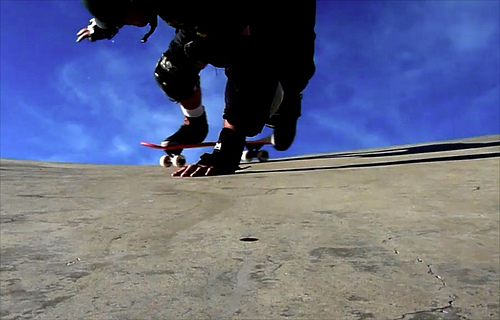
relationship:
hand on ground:
[173, 157, 239, 185] [0, 160, 499, 318]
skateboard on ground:
[140, 138, 271, 165] [0, 160, 499, 318]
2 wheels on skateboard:
[159, 155, 188, 166] [140, 138, 271, 165]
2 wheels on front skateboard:
[159, 155, 188, 166] [140, 138, 271, 165]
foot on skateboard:
[160, 115, 210, 148] [140, 138, 271, 165]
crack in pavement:
[320, 213, 470, 318] [0, 160, 499, 318]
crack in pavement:
[2, 212, 114, 319] [0, 160, 499, 318]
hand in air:
[76, 19, 117, 48] [68, 16, 130, 56]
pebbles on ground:
[104, 177, 326, 205] [0, 160, 499, 318]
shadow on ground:
[291, 141, 499, 172] [0, 160, 499, 318]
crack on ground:
[320, 213, 470, 318] [0, 160, 499, 318]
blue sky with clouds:
[0, 1, 494, 138] [14, 15, 484, 139]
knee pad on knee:
[154, 49, 203, 102] [161, 62, 199, 99]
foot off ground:
[270, 97, 304, 154] [0, 160, 499, 318]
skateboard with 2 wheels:
[140, 138, 271, 165] [159, 155, 188, 166]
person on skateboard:
[78, 0, 315, 174] [140, 138, 271, 165]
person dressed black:
[78, 0, 315, 174] [226, 0, 316, 85]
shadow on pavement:
[291, 141, 499, 172] [0, 160, 499, 318]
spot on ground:
[234, 231, 266, 252] [0, 160, 499, 318]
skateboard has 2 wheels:
[140, 138, 271, 165] [159, 155, 188, 166]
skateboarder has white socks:
[78, 0, 315, 174] [179, 107, 206, 116]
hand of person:
[173, 157, 239, 185] [78, 0, 315, 174]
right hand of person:
[76, 19, 117, 48] [78, 0, 315, 174]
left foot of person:
[270, 97, 304, 154] [78, 0, 315, 174]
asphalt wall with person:
[0, 160, 499, 318] [78, 0, 315, 174]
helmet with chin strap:
[85, 0, 167, 23] [138, 17, 168, 45]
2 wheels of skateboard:
[159, 155, 188, 166] [140, 138, 271, 165]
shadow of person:
[291, 141, 499, 172] [78, 0, 315, 174]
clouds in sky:
[14, 15, 484, 139] [0, 1, 494, 138]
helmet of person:
[85, 0, 167, 23] [78, 0, 315, 174]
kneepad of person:
[154, 49, 203, 102] [78, 0, 315, 174]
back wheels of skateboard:
[240, 148, 270, 164] [140, 138, 271, 165]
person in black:
[78, 0, 315, 174] [226, 0, 316, 85]